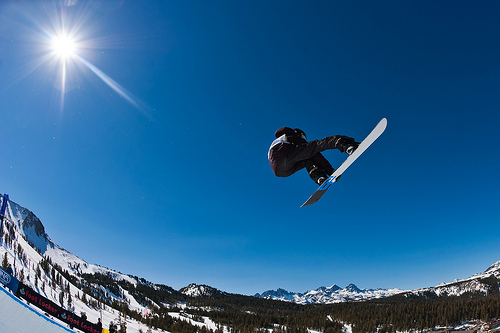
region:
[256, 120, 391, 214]
person in mid air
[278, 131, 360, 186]
legs of a person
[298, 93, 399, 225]
snow board in mid air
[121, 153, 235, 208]
clear blue sky with no clouds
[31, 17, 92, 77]
bright sun in the sky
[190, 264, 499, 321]
trees and mountains in background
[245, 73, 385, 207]
person on his snow board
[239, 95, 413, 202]
person wearing jacket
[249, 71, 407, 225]
person wearing a goggle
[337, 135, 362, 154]
feet of a person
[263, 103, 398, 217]
a person on a snow board.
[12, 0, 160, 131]
the sun shining brightly in the sky.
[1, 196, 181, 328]
a snow covered ski slope.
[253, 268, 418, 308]
mountains towering above a forest.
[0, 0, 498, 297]
a crystal clear blue sky.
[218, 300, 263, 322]
a section of a forest on a mountain.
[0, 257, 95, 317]
trees lining a ski slope.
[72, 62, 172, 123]
a ray of sun shine.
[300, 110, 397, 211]
a white and blue snowboard.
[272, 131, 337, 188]
a man wearing dark pants.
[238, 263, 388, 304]
mountains is covered with snow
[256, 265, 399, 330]
mountains is covered with snow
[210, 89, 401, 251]
a person with snowboard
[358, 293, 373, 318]
par tof a forert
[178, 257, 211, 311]
aprt of a hill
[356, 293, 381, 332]
part of a forest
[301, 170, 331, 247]
aprt of a board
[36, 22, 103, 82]
The rays of a the sun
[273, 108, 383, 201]
an air born skater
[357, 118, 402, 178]
a skate board in the air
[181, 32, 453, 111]
a blue sky above the hills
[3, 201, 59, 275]
a hill covered with snow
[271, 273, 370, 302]
hills in the distant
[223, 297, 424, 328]
trees along the heals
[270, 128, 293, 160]
the back of a skater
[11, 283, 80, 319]
a banner on the slopes of a hill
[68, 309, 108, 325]
people standing near a banner